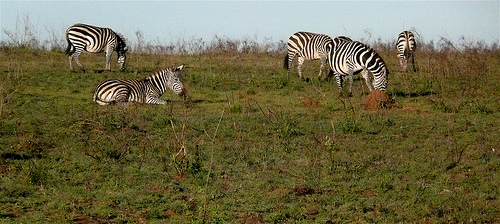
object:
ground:
[0, 54, 499, 223]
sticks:
[122, 26, 294, 58]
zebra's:
[60, 23, 422, 105]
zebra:
[89, 63, 191, 106]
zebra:
[61, 24, 132, 74]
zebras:
[324, 30, 419, 98]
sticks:
[82, 110, 250, 219]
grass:
[0, 47, 499, 223]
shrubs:
[68, 103, 381, 221]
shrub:
[363, 80, 423, 129]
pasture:
[44, 90, 493, 220]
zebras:
[60, 23, 419, 108]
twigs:
[150, 110, 240, 185]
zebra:
[391, 31, 418, 74]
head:
[367, 77, 394, 103]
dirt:
[365, 90, 396, 109]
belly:
[82, 40, 107, 53]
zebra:
[284, 24, 413, 127]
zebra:
[327, 35, 392, 107]